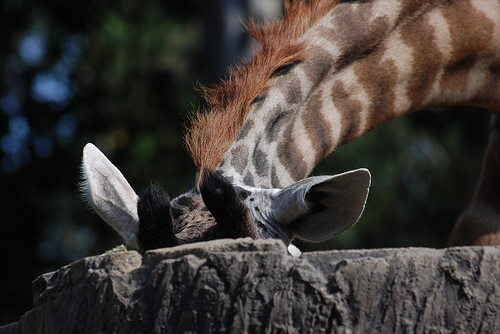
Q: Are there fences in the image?
A: No, there are no fences.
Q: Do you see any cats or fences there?
A: No, there are no fences or cats.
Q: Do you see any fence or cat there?
A: No, there are no fences or cats.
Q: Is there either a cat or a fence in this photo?
A: No, there are no fences or cats.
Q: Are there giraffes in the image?
A: Yes, there is a giraffe.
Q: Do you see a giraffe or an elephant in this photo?
A: Yes, there is a giraffe.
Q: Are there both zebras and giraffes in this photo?
A: No, there is a giraffe but no zebras.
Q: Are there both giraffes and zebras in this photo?
A: No, there is a giraffe but no zebras.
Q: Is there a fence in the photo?
A: No, there are no fences.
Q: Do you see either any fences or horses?
A: No, there are no fences or horses.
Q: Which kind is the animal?
A: The animal is a giraffe.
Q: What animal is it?
A: The animal is a giraffe.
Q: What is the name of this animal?
A: That is a giraffe.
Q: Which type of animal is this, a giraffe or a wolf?
A: That is a giraffe.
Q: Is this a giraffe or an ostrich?
A: This is a giraffe.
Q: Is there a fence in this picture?
A: No, there are no fences.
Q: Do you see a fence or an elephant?
A: No, there are no fences or elephants.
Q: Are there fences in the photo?
A: No, there are no fences.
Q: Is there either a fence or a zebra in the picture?
A: No, there are no fences or zebras.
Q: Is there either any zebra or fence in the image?
A: No, there are no fences or zebras.